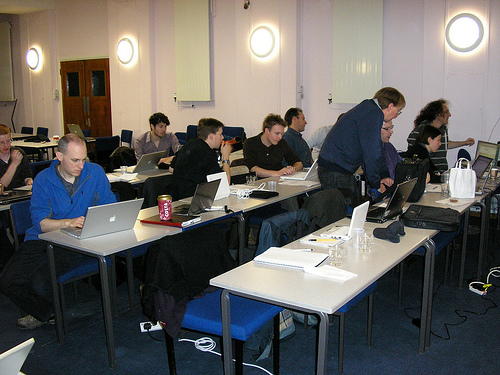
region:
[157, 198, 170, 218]
a red can of coca cola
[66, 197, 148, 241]
a silver macbook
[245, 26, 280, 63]
a bright lamp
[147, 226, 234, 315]
a black jacket on a seat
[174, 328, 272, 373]
a white cord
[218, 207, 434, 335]
a long white cluttered table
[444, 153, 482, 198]
a white hand bag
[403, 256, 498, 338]
a mess of cables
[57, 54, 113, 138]
brown wooden double doors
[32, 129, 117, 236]
a man in a blue sweater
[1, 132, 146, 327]
A man using a laptop.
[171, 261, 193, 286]
Part of a black jacket.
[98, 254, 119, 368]
A grey table leg.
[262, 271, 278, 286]
Part of the table.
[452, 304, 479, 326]
Part of a black wire.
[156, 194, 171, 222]
A colorful cup.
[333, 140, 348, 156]
Part of a blue jacket.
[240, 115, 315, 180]
A man using a laptop.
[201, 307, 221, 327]
Part of the blue seat.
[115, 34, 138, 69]
A light on a wall.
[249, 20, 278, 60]
light in classroom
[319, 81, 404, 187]
teacher helping student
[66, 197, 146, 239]
a laptop computer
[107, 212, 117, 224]
apple symbol on computer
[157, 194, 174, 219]
can of drink on table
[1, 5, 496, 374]
students working on computers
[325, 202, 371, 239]
white laptop on table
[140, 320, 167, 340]
cord plugged in power strip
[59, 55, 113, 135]
a brown double door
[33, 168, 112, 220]
man wearing blue sweater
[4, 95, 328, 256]
people on laptops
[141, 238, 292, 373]
a blue chair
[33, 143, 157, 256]
a man on a silver laptop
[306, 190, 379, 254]
a white laptop on a table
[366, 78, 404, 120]
a man wearing glasses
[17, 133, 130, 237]
a man wearing a blue sweatshirt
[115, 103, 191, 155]
a man wearing a button up shirt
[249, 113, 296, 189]
a man wearing a black shirt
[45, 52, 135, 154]
two brown wooden doors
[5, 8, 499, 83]
circle lights on a wall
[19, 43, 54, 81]
light fixture on a wall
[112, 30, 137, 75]
light fixture on a wall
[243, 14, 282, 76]
light fixture on a wall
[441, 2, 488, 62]
light fixture on a wall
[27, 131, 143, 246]
man typing on a laptop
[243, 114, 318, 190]
man typing on a laptop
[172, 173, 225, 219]
laptop sitting on a table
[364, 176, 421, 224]
laptop sitting on a table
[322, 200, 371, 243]
laptop sitting on a table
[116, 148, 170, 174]
laptop sitting on a table